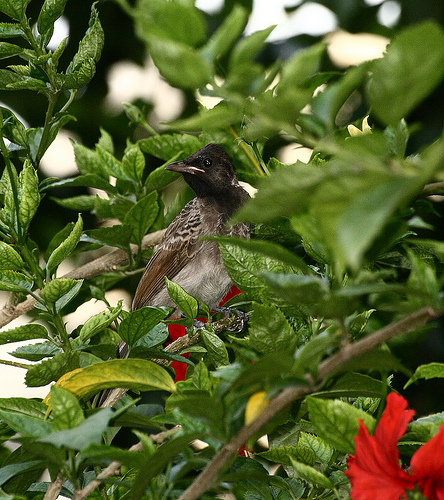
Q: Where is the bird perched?
A: In a tree.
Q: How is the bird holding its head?
A: To it's right.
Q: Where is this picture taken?
A: The forest.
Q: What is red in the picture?
A: A flower.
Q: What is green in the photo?
A: The leaves.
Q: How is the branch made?
A: Of wood.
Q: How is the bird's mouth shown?
A: Closed.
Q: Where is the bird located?
A: In a plant.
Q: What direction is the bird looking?
A: Left.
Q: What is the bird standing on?
A: Branch.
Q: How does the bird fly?
A: Wings.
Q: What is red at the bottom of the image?
A: Flower.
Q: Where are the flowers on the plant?
A: Bottom of image.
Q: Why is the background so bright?
A: Lights.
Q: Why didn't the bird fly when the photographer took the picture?
A: Zoom.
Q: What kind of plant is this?
A: Bush.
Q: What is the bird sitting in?
A: A plant.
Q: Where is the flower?
A: In the plant.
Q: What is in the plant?
A: Bird.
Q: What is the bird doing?
A: Looking around.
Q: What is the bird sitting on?
A: A limb.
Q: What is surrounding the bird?
A: Leaves.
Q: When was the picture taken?
A: Daytime.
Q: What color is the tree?
A: Green.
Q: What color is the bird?
A: Brown and black.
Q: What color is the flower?
A: Red.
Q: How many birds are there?
A: One.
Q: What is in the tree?
A: A bird.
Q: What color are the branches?
A: Brown.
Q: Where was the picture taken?
A: In a bush.